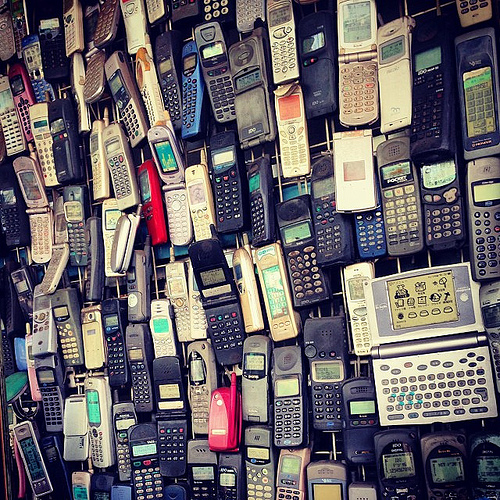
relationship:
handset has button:
[174, 41, 209, 149] [188, 77, 194, 85]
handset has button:
[174, 41, 209, 149] [187, 77, 190, 85]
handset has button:
[174, 41, 209, 149] [184, 97, 194, 107]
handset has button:
[174, 41, 209, 149] [189, 109, 194, 119]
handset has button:
[174, 41, 209, 149] [179, 106, 189, 112]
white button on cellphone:
[215, 399, 225, 406] [208, 373, 242, 455]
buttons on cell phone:
[213, 169, 274, 229] [194, 138, 263, 243]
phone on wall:
[142, 121, 191, 249] [2, 4, 498, 499]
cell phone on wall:
[126, 422, 166, 499] [2, 4, 498, 499]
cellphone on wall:
[329, 126, 379, 216] [2, 4, 498, 499]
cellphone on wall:
[340, 370, 383, 470] [2, 4, 498, 499]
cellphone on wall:
[202, 371, 242, 452] [2, 4, 498, 499]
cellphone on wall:
[180, 162, 220, 239] [2, 4, 498, 499]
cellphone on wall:
[335, 0, 377, 127] [2, 4, 498, 499]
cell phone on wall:
[277, 193, 330, 310] [2, 4, 498, 499]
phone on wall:
[77, 371, 112, 467] [26, 60, 469, 486]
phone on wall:
[153, 363, 184, 465] [131, 42, 489, 429]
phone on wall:
[186, 342, 215, 434] [131, 42, 489, 429]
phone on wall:
[188, 436, 216, 496] [131, 42, 489, 429]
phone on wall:
[268, 349, 308, 453] [44, 198, 445, 482]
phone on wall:
[237, 339, 268, 422] [44, 198, 445, 482]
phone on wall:
[243, 428, 276, 498] [44, 198, 445, 482]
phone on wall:
[278, 444, 308, 497] [44, 198, 445, 482]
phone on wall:
[209, 130, 245, 233] [138, 70, 374, 304]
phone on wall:
[187, 170, 212, 240] [138, 70, 374, 304]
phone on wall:
[250, 166, 270, 236] [138, 70, 374, 304]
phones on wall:
[0, 7, 498, 494] [169, 126, 340, 346]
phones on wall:
[0, 7, 498, 494] [2, 4, 498, 499]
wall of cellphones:
[2, 4, 498, 499] [5, 9, 498, 499]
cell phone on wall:
[10, 420, 55, 498] [2, 4, 498, 499]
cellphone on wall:
[201, 138, 245, 231] [2, 4, 498, 499]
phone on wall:
[302, 320, 352, 433] [149, 204, 455, 475]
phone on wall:
[181, 169, 219, 243] [102, 99, 428, 386]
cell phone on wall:
[59, 186, 95, 260] [15, 119, 275, 402]